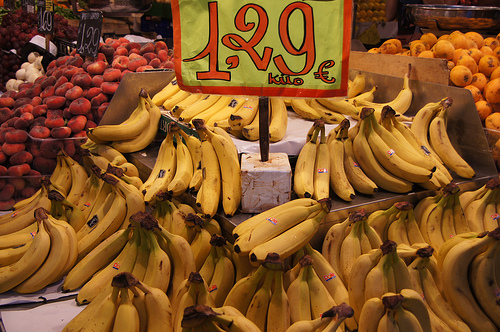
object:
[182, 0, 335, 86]
price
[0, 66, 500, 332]
bananas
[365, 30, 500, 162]
oranges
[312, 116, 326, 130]
stem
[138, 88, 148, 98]
stem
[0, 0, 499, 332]
fruit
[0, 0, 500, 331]
market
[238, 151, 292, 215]
block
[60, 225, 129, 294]
banana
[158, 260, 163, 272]
spot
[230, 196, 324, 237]
banana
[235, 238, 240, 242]
spot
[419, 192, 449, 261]
banana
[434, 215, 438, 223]
spot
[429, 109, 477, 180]
banana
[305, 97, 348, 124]
banana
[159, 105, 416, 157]
paper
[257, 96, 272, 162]
pole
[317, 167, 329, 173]
sticker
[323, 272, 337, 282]
sticker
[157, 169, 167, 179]
sticker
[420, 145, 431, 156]
sticker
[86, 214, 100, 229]
sticker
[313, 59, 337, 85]
euro symbol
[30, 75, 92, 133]
peaches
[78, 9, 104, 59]
sign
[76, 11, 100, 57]
price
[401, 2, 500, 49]
scale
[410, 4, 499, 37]
bowl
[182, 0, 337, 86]
black outline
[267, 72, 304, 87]
kilos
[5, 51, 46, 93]
pears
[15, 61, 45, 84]
coconuts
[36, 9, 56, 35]
sign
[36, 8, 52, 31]
price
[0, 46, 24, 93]
plums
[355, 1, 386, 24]
lemons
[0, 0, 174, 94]
back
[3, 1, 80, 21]
vegetables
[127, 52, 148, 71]
peach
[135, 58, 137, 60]
bruise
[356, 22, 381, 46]
sign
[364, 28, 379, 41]
price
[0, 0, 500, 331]
scene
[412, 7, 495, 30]
reflection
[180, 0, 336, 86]
'1,29 kilo €'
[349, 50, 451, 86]
thin wood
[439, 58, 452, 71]
chewed corner